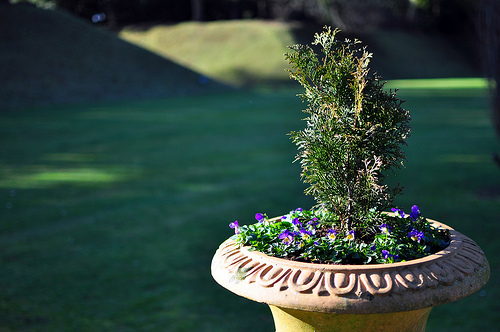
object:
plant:
[281, 22, 415, 250]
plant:
[226, 215, 258, 238]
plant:
[276, 229, 305, 257]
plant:
[370, 243, 410, 265]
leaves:
[301, 133, 326, 169]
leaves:
[374, 235, 397, 249]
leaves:
[256, 215, 296, 227]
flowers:
[222, 194, 457, 265]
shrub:
[287, 31, 406, 263]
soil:
[273, 211, 435, 296]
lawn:
[2, 76, 493, 329]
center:
[248, 210, 435, 260]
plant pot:
[209, 202, 493, 329]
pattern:
[221, 235, 481, 292]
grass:
[101, 110, 251, 190]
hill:
[35, 5, 343, 113]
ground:
[404, 175, 425, 192]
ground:
[410, 172, 447, 218]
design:
[226, 255, 496, 305]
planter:
[188, 200, 490, 310]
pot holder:
[220, 205, 487, 330]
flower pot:
[209, 207, 491, 330]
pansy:
[406, 200, 423, 219]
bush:
[284, 28, 409, 224]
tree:
[275, 53, 420, 207]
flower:
[325, 227, 338, 244]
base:
[210, 207, 492, 312]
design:
[229, 263, 476, 297]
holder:
[207, 259, 492, 330]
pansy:
[268, 222, 445, 256]